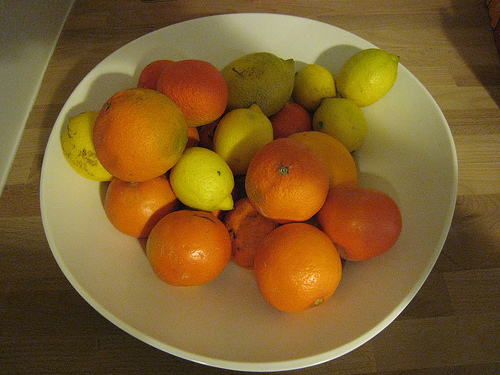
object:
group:
[60, 48, 403, 312]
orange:
[146, 208, 232, 285]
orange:
[253, 222, 342, 313]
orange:
[317, 183, 403, 260]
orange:
[103, 175, 177, 237]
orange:
[137, 59, 176, 94]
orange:
[244, 138, 331, 223]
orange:
[224, 196, 281, 270]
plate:
[39, 12, 459, 373]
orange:
[93, 87, 189, 183]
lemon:
[335, 48, 398, 107]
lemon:
[169, 147, 234, 212]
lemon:
[313, 97, 365, 153]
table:
[0, 1, 498, 374]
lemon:
[60, 111, 114, 186]